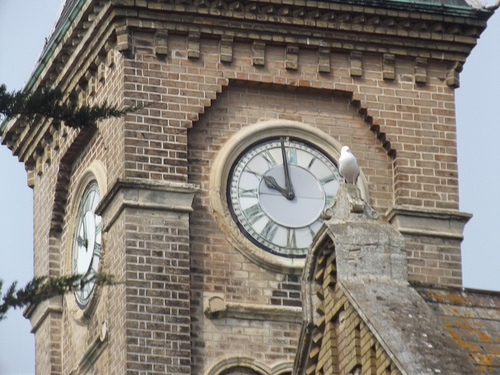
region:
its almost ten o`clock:
[226, 132, 349, 234]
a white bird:
[314, 135, 378, 215]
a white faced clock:
[187, 112, 376, 253]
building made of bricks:
[102, 47, 197, 357]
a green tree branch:
[2, 72, 147, 137]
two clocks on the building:
[38, 129, 378, 324]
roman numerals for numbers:
[230, 131, 320, 184]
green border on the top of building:
[0, 0, 79, 127]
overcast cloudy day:
[1, 5, 87, 94]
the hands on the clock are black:
[228, 117, 308, 207]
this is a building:
[124, 40, 366, 101]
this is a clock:
[242, 152, 333, 221]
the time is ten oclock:
[257, 136, 303, 203]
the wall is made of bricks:
[142, 59, 200, 136]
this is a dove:
[338, 145, 361, 184]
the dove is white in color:
[337, 142, 358, 184]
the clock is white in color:
[249, 159, 329, 229]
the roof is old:
[378, 266, 417, 350]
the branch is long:
[28, 87, 99, 127]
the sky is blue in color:
[470, 122, 495, 165]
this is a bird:
[339, 140, 359, 190]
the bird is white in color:
[340, 154, 355, 171]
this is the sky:
[466, 92, 493, 201]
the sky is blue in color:
[473, 53, 486, 135]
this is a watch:
[247, 142, 315, 245]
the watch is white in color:
[286, 202, 311, 214]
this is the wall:
[122, 57, 195, 182]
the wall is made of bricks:
[170, 79, 207, 111]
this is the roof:
[408, 272, 495, 366]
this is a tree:
[7, 85, 125, 131]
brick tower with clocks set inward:
[13, 5, 473, 361]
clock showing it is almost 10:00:
[221, 102, 341, 262]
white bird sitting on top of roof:
[325, 130, 370, 225]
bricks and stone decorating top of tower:
[112, 5, 482, 90]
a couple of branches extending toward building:
[6, 65, 158, 325]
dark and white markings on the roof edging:
[332, 215, 482, 370]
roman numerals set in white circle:
[225, 110, 335, 255]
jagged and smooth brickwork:
[177, 62, 398, 162]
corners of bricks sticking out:
[300, 255, 330, 365]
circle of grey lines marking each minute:
[223, 120, 341, 260]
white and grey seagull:
[339, 144, 362, 186]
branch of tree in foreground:
[0, 65, 155, 131]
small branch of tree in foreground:
[0, 267, 125, 322]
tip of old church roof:
[292, 183, 498, 373]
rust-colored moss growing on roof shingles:
[428, 283, 498, 366]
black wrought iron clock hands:
[262, 132, 299, 204]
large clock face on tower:
[204, 113, 371, 273]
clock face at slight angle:
[65, 158, 107, 321]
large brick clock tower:
[3, 0, 464, 374]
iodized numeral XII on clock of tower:
[281, 142, 298, 164]